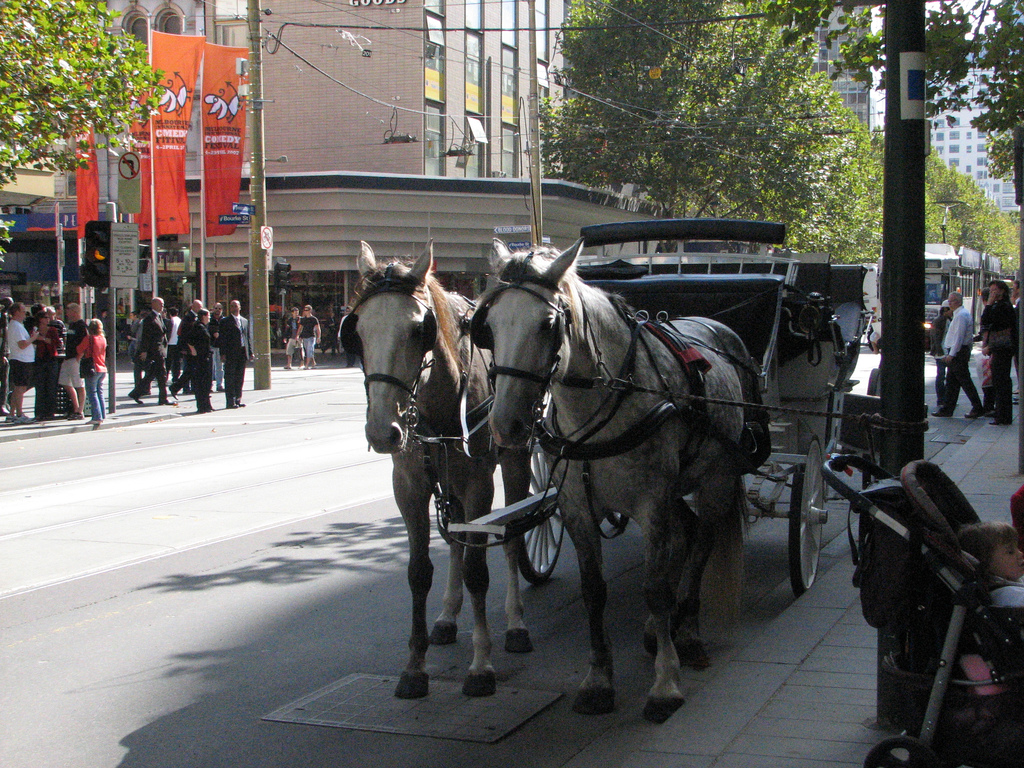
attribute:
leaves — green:
[49, 22, 99, 70]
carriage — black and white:
[438, 208, 888, 591]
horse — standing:
[336, 208, 760, 647]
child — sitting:
[923, 482, 1016, 563]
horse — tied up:
[396, 284, 794, 604]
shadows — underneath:
[197, 525, 435, 726]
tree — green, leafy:
[521, 22, 893, 245]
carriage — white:
[480, 234, 878, 665]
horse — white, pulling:
[303, 262, 844, 753]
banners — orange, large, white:
[79, 0, 270, 215]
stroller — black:
[764, 474, 953, 658]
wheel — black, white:
[737, 446, 921, 598]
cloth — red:
[610, 297, 788, 412]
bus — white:
[856, 240, 1021, 375]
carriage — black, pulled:
[602, 240, 938, 580]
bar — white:
[429, 471, 596, 593]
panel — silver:
[272, 622, 545, 743]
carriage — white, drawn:
[529, 175, 843, 567]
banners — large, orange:
[155, 36, 236, 224]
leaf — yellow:
[740, 39, 831, 109]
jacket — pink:
[80, 326, 111, 370]